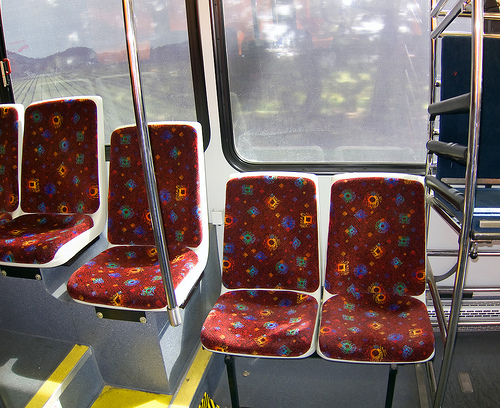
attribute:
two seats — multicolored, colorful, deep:
[188, 150, 463, 382]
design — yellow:
[261, 189, 297, 215]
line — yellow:
[162, 330, 219, 405]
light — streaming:
[237, 7, 443, 70]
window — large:
[215, 5, 445, 174]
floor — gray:
[8, 315, 220, 406]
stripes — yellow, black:
[196, 385, 216, 406]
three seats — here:
[66, 119, 443, 369]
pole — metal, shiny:
[115, 4, 193, 328]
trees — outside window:
[236, 5, 428, 133]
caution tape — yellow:
[29, 335, 94, 406]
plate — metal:
[91, 305, 147, 331]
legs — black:
[220, 347, 404, 407]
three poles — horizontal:
[414, 84, 479, 215]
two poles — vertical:
[422, 3, 488, 408]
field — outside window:
[12, 9, 459, 158]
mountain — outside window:
[13, 47, 135, 82]